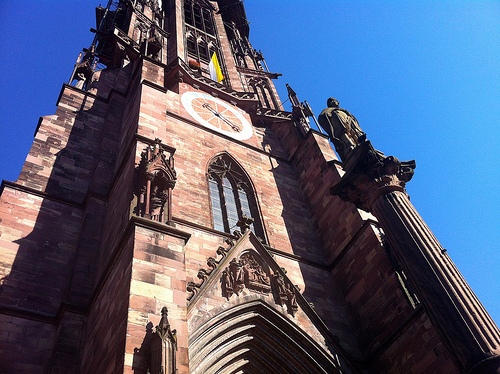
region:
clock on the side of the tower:
[179, 90, 268, 147]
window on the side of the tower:
[193, 143, 273, 239]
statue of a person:
[311, 93, 380, 162]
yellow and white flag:
[206, 48, 222, 77]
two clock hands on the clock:
[198, 98, 247, 134]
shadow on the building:
[1, 66, 149, 370]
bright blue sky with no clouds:
[0, 0, 499, 322]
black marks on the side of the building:
[143, 237, 183, 264]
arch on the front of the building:
[180, 213, 355, 372]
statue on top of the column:
[318, 90, 498, 364]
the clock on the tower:
[175, 83, 251, 138]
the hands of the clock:
[196, 95, 241, 131]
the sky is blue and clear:
[286, 17, 474, 98]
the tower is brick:
[3, 3, 398, 370]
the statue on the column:
[301, 86, 398, 165]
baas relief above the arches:
[214, 253, 308, 310]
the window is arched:
[201, 133, 271, 240]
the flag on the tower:
[197, 46, 238, 82]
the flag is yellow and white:
[209, 46, 234, 90]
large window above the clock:
[176, 3, 235, 90]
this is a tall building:
[3, 33, 474, 366]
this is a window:
[201, 145, 288, 269]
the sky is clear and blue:
[346, 24, 411, 74]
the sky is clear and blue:
[269, 31, 337, 78]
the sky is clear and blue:
[397, 67, 478, 149]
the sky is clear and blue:
[309, 47, 386, 96]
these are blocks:
[141, 236, 180, 278]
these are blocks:
[174, 145, 208, 201]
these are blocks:
[253, 160, 305, 235]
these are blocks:
[141, 98, 205, 155]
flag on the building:
[186, 53, 233, 83]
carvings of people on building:
[215, 250, 310, 305]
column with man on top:
[306, 90, 499, 362]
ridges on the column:
[373, 193, 499, 351]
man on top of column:
[313, 90, 370, 153]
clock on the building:
[175, 93, 257, 139]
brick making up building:
[275, 157, 305, 187]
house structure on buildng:
[135, 135, 179, 224]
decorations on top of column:
[325, 149, 426, 197]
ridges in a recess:
[201, 323, 312, 366]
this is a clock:
[172, 81, 260, 139]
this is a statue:
[304, 72, 407, 179]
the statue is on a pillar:
[307, 77, 383, 176]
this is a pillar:
[329, 138, 494, 373]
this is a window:
[195, 137, 290, 248]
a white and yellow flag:
[197, 48, 235, 95]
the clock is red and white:
[165, 65, 272, 148]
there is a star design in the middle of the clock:
[160, 70, 267, 159]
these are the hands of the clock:
[190, 81, 262, 138]